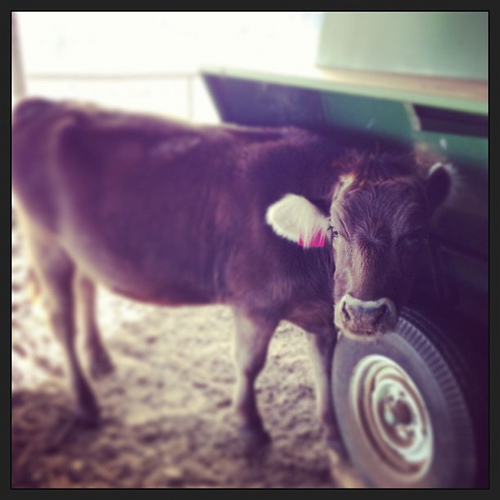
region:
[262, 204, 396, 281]
the ear is big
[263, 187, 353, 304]
the ear is big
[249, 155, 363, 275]
the ear is big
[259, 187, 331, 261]
the ear is big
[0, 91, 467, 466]
little brown cow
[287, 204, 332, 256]
square red tag in the cows ear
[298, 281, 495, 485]
black rubber automobile tire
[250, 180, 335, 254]
fuzzy white cow ear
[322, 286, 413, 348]
black cow nose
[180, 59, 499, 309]
forest green painted side of a vehicle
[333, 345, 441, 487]
silver metal wheel well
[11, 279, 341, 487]
grayish brown dirt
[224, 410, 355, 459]
little black cow hooves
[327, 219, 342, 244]
light brown baby cow eye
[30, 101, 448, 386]
brown cow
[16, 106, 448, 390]
standing brown cow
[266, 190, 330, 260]
right ear of brown cow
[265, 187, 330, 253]
right red ear of brown cow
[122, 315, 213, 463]
brown dirt under brown cow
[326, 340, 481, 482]
black and white tire of truck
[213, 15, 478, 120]
green and brown truck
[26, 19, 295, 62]
clear window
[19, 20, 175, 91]
white pane on window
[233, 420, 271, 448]
gray hoof of brown cow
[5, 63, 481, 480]
a young cow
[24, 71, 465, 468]
a young brown cow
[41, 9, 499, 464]
a cow standing next to vehicle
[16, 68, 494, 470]
a cow standing next to machine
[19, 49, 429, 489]
a cow standing in dirt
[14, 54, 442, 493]
a cow standing inside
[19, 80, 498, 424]
a young cow inside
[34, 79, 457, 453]
a young cow looking to side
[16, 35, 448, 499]
a young cow that is brown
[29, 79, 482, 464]
a cow on dirt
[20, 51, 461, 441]
young brown cow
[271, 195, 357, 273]
a red tag on the cows ear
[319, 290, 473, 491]
small black tire on a wheel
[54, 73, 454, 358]
dark brown furry cow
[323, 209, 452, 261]
large black cow eyes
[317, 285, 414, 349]
light brown and white snout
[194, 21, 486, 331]
green tractor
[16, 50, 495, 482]
brown cow standing next to a tractor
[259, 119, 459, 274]
large white ears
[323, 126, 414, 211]
tuft of brown hair